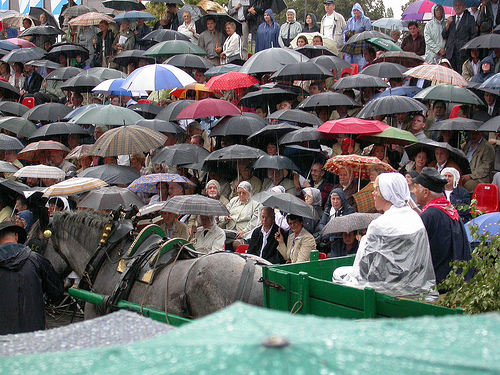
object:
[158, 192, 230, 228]
umbrella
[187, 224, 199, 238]
hand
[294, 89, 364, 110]
umbrella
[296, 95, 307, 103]
hand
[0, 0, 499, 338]
group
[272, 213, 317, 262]
people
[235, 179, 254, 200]
hat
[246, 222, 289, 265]
jacket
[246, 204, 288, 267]
man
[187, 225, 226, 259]
shirt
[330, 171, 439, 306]
woman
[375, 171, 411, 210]
hat on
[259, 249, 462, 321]
trailer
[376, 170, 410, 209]
cap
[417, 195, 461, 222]
neckerchief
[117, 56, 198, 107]
umbrella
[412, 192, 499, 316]
plant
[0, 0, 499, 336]
crowd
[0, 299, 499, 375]
wagon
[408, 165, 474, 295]
man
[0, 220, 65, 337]
man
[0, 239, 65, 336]
clothes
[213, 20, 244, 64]
spectators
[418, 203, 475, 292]
clothing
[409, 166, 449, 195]
hat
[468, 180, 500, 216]
chair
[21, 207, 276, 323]
horse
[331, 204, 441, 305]
covering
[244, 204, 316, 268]
couple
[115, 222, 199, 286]
saddle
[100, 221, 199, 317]
embellishments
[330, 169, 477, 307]
couple